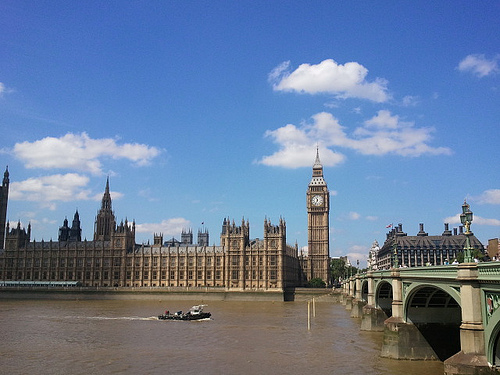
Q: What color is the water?
A: The water looks brown.